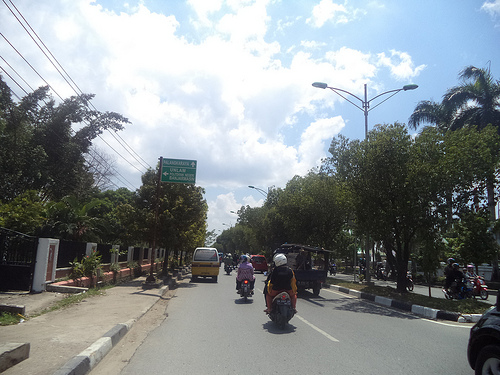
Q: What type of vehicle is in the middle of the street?
A: Motorcycle.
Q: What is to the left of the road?
A: A fence.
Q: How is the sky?
A: Blue with heavy white clouds.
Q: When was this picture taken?
A: Daytime.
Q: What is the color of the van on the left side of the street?
A: Yellow.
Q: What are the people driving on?
A: A road.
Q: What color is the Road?
A: Black.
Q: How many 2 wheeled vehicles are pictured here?
A: 3.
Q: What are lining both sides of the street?
A: Trees.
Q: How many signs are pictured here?
A: 1.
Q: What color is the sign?
A: Green.